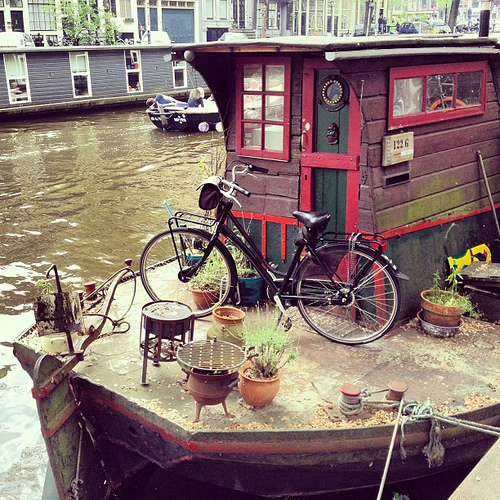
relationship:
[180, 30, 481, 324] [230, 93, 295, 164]
building has window